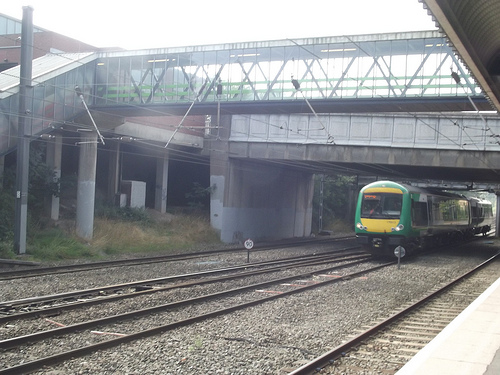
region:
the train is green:
[356, 169, 457, 253]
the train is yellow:
[355, 180, 418, 245]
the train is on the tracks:
[306, 177, 412, 278]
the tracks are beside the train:
[351, 280, 426, 374]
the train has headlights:
[349, 216, 412, 236]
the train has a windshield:
[364, 188, 406, 218]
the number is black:
[241, 240, 257, 250]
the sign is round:
[233, 231, 260, 251]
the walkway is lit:
[194, 43, 413, 63]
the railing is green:
[237, 73, 402, 95]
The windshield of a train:
[360, 193, 405, 222]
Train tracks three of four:
[122, 304, 214, 329]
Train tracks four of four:
[407, 296, 454, 318]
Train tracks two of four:
[72, 286, 128, 299]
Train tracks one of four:
[89, 254, 139, 275]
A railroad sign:
[236, 234, 256, 261]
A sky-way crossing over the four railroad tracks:
[226, 104, 496, 151]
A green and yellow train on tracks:
[354, 179, 476, 246]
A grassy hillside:
[112, 218, 184, 243]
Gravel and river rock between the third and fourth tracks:
[298, 301, 340, 333]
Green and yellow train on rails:
[344, 178, 496, 244]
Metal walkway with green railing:
[117, 21, 474, 116]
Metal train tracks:
[125, 300, 202, 332]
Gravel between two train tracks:
[234, 279, 374, 360]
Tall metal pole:
[7, 0, 47, 254]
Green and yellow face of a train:
[338, 172, 409, 244]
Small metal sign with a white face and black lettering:
[239, 231, 259, 261]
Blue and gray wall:
[219, 167, 299, 231]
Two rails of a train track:
[102, 307, 143, 345]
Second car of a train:
[453, 185, 495, 235]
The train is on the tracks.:
[328, 163, 468, 280]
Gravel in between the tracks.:
[253, 289, 355, 366]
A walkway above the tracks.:
[93, 39, 497, 133]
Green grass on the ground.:
[93, 201, 188, 243]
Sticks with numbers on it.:
[238, 226, 260, 270]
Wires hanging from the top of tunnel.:
[289, 85, 362, 154]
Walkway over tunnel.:
[83, 45, 498, 100]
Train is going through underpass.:
[345, 166, 499, 253]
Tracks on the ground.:
[65, 255, 257, 367]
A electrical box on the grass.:
[123, 171, 157, 220]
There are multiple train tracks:
[28, 257, 487, 363]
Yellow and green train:
[342, 178, 489, 265]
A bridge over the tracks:
[88, 47, 469, 172]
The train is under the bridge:
[306, 178, 485, 292]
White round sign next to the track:
[237, 238, 264, 278]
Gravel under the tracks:
[71, 253, 483, 353]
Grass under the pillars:
[28, 167, 233, 243]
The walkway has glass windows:
[18, 35, 431, 132]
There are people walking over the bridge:
[207, 73, 474, 100]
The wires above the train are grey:
[71, 29, 463, 199]